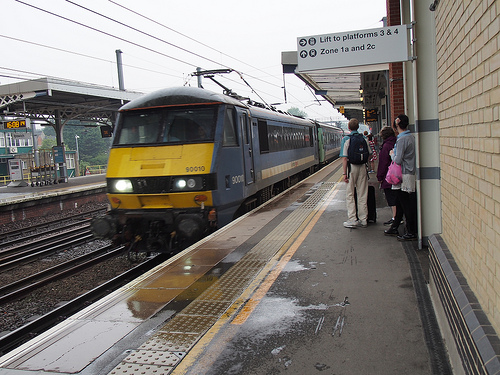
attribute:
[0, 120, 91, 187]
station — gas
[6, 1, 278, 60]
clouds — white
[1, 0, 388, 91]
sky — blue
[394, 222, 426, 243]
shoe — black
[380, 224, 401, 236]
shoe — black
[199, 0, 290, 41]
clouds — white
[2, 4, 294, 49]
sky — blue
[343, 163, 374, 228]
pants — tan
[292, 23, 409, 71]
sign — hung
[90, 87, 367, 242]
car — train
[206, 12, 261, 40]
clouds — white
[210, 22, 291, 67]
sky — blue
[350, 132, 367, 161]
bag — black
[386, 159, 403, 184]
bag — pink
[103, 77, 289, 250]
rail — light, grey, yellow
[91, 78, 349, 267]
train — yellow, grey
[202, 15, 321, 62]
sky — blue, white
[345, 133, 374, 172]
backpack — black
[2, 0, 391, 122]
sky — blue